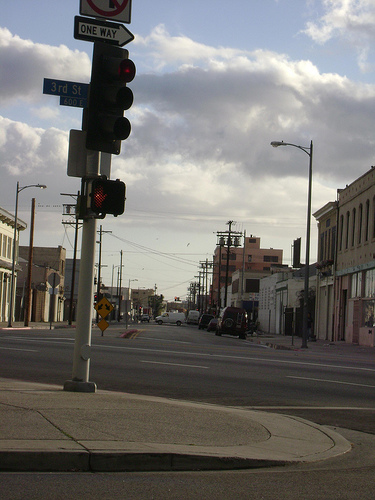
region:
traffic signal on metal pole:
[55, 6, 120, 382]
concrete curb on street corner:
[0, 386, 327, 469]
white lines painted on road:
[127, 346, 234, 389]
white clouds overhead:
[165, 65, 301, 153]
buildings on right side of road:
[196, 200, 373, 322]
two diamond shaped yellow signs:
[95, 300, 119, 339]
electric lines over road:
[108, 235, 221, 286]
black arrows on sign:
[88, 302, 115, 315]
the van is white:
[148, 309, 191, 329]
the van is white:
[147, 305, 194, 329]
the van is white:
[145, 305, 188, 330]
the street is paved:
[130, 353, 243, 410]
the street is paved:
[121, 336, 249, 393]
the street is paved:
[131, 345, 273, 405]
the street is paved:
[126, 335, 286, 410]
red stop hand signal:
[81, 174, 127, 218]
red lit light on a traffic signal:
[82, 39, 136, 155]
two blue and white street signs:
[42, 76, 90, 108]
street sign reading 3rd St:
[40, 76, 91, 96]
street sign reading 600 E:
[59, 94, 88, 107]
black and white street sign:
[72, 13, 134, 48]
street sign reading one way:
[73, 13, 138, 47]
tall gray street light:
[267, 136, 318, 350]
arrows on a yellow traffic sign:
[92, 296, 116, 335]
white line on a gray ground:
[136, 353, 213, 371]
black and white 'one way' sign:
[73, 15, 135, 48]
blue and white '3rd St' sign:
[41, 74, 90, 99]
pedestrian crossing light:
[85, 176, 125, 215]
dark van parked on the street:
[214, 303, 249, 340]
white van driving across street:
[155, 308, 187, 325]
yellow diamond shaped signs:
[95, 295, 116, 331]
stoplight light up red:
[82, 37, 138, 156]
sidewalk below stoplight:
[0, 375, 353, 474]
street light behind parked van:
[270, 137, 319, 349]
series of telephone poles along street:
[186, 216, 244, 310]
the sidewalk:
[96, 410, 154, 437]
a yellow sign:
[95, 298, 111, 319]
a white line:
[144, 355, 208, 372]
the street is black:
[232, 368, 276, 391]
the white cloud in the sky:
[156, 160, 209, 203]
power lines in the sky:
[143, 241, 181, 269]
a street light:
[267, 138, 294, 151]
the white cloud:
[13, 143, 52, 169]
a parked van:
[218, 305, 248, 339]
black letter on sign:
[80, 21, 88, 35]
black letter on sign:
[83, 24, 91, 33]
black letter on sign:
[90, 22, 97, 38]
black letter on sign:
[98, 26, 110, 38]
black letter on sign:
[104, 28, 113, 41]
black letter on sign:
[111, 28, 119, 39]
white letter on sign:
[55, 83, 65, 94]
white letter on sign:
[60, 82, 68, 93]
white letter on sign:
[68, 84, 77, 96]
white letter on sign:
[74, 82, 81, 97]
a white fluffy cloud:
[219, 156, 239, 175]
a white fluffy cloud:
[188, 205, 216, 231]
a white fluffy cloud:
[266, 197, 300, 216]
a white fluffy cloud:
[174, 165, 207, 199]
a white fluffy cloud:
[257, 146, 274, 169]